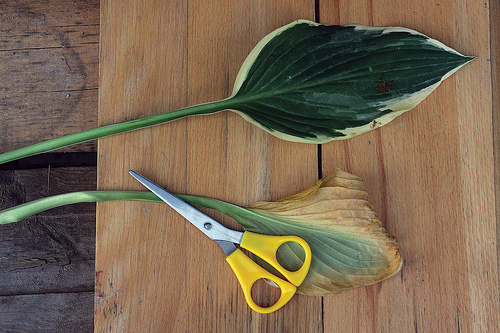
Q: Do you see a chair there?
A: No, there are no chairs.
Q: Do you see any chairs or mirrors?
A: No, there are no chairs or mirrors.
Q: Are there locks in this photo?
A: No, there are no locks.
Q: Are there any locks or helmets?
A: No, there are no locks or helmets.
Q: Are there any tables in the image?
A: Yes, there is a table.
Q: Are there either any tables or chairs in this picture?
A: Yes, there is a table.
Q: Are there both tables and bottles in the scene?
A: No, there is a table but no bottles.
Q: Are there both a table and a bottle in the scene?
A: No, there is a table but no bottles.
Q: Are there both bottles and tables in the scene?
A: No, there is a table but no bottles.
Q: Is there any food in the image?
A: No, there is no food.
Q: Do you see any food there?
A: No, there is no food.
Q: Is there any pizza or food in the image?
A: No, there are no food or pizzas.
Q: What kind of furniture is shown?
A: The furniture is a table.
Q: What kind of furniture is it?
A: The piece of furniture is a table.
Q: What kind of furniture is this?
A: This is a table.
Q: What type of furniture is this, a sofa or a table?
A: This is a table.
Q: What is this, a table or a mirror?
A: This is a table.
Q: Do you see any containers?
A: No, there are no containers.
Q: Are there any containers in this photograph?
A: No, there are no containers.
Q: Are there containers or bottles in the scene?
A: No, there are no containers or bottles.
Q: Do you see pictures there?
A: No, there are no pictures.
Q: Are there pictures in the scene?
A: No, there are no pictures.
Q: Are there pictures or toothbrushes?
A: No, there are no pictures or toothbrushes.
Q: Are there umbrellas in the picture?
A: No, there are no umbrellas.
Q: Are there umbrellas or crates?
A: No, there are no umbrellas or crates.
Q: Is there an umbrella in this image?
A: No, there are no umbrellas.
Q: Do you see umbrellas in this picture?
A: No, there are no umbrellas.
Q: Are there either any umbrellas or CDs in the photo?
A: No, there are no umbrellas or cds.